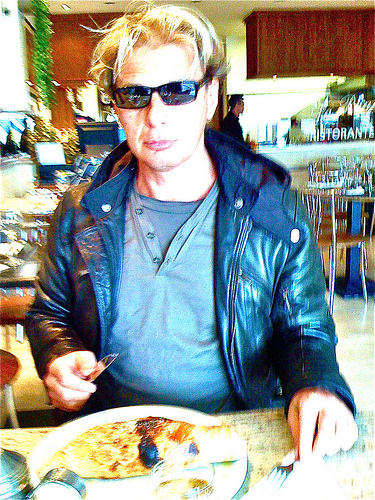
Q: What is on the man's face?
A: Sunglasses.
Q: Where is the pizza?
A: On the plate.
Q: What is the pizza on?
A: A plate.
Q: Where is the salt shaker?
A: By the plate.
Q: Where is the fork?
A: In the right hand.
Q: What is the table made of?
A: Wood.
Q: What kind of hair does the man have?
A: Blonde.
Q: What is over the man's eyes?
A: Sunglasses.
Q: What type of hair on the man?
A: Long blonde hair.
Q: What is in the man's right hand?
A: A knife.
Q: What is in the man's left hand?
A: A fork.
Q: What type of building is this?
A: A restaurant.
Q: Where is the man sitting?
A: At a table.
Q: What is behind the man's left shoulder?
A: A person.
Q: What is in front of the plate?
A: A glass.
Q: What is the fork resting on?
A: A napkin.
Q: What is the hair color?
A: Blonde.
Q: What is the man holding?
A: Fork.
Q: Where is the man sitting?
A: Table.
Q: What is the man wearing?
A: Jacket.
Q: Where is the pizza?
A: Plate.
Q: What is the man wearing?
A: Sunglasses.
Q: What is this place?
A: A restaurant.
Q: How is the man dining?
A: While standing.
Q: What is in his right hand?
A: A knife.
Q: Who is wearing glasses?
A: The diner.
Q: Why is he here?
A: To eat a meal.